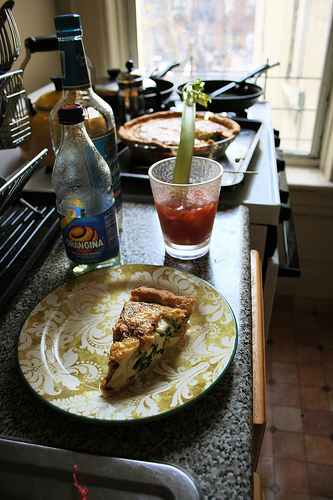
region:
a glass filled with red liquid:
[154, 88, 220, 262]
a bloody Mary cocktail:
[142, 85, 222, 267]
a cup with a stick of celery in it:
[149, 85, 222, 261]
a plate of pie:
[30, 270, 226, 409]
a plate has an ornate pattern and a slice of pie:
[49, 273, 240, 418]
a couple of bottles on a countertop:
[26, 14, 128, 259]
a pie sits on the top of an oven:
[125, 110, 236, 154]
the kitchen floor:
[277, 316, 331, 488]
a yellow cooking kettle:
[17, 23, 111, 170]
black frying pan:
[164, 63, 289, 109]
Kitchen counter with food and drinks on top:
[5, 135, 328, 497]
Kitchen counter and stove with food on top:
[0, 0, 329, 497]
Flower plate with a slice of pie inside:
[22, 259, 237, 423]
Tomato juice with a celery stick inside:
[147, 85, 232, 261]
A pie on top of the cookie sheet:
[104, 103, 260, 190]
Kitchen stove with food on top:
[14, 0, 317, 221]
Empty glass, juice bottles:
[19, 10, 134, 264]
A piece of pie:
[90, 282, 193, 394]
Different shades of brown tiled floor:
[268, 288, 331, 496]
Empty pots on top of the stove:
[95, 58, 271, 118]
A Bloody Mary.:
[143, 78, 231, 261]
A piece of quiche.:
[104, 278, 187, 385]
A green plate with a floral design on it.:
[23, 261, 231, 403]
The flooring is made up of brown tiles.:
[274, 347, 320, 473]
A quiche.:
[115, 105, 236, 158]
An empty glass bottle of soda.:
[40, 94, 119, 268]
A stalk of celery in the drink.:
[172, 81, 201, 209]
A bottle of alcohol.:
[46, 11, 125, 234]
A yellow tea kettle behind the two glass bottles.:
[12, 35, 112, 163]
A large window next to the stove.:
[118, 2, 328, 176]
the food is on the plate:
[91, 279, 198, 399]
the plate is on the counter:
[35, 268, 239, 433]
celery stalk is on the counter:
[171, 77, 209, 203]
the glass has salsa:
[148, 156, 236, 266]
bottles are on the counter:
[43, 22, 123, 273]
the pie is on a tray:
[128, 100, 257, 162]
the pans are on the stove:
[185, 70, 288, 127]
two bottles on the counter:
[43, 12, 128, 284]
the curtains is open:
[124, 2, 332, 136]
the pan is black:
[182, 81, 269, 110]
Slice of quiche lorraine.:
[98, 284, 193, 397]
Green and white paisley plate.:
[14, 264, 241, 428]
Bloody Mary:
[145, 156, 230, 260]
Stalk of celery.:
[169, 78, 214, 213]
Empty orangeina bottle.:
[48, 103, 126, 277]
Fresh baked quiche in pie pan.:
[117, 99, 241, 161]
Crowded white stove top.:
[37, 77, 278, 200]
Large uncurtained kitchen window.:
[135, 0, 326, 163]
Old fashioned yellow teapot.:
[9, 18, 117, 170]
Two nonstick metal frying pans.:
[84, 54, 280, 117]